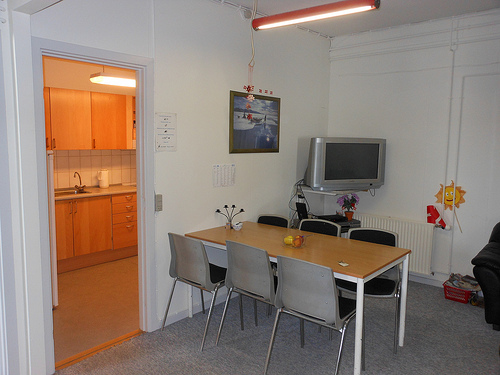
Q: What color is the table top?
A: Brown.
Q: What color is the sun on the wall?
A: Yellow.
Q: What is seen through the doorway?
A: Kitchen.